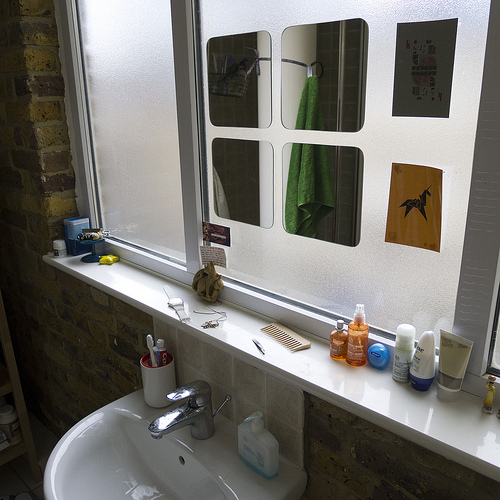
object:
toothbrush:
[147, 335, 156, 367]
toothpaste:
[153, 338, 168, 367]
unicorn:
[399, 185, 433, 223]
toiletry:
[436, 328, 473, 401]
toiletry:
[392, 324, 415, 384]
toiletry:
[366, 342, 389, 369]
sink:
[33, 410, 313, 498]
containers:
[49, 214, 83, 254]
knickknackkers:
[71, 220, 117, 269]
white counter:
[131, 251, 391, 416]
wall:
[1, 0, 500, 500]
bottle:
[408, 331, 436, 391]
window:
[197, 0, 490, 361]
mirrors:
[204, 15, 369, 249]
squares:
[204, 13, 368, 243]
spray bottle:
[342, 301, 370, 364]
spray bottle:
[330, 319, 347, 359]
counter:
[330, 369, 375, 404]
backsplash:
[151, 313, 309, 468]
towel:
[285, 74, 342, 235]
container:
[228, 407, 285, 484]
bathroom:
[2, 0, 497, 497]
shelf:
[27, 232, 497, 484]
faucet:
[147, 378, 213, 444]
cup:
[140, 353, 178, 405]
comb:
[259, 322, 311, 352]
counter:
[46, 248, 498, 479]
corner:
[26, 98, 118, 278]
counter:
[253, 345, 496, 466]